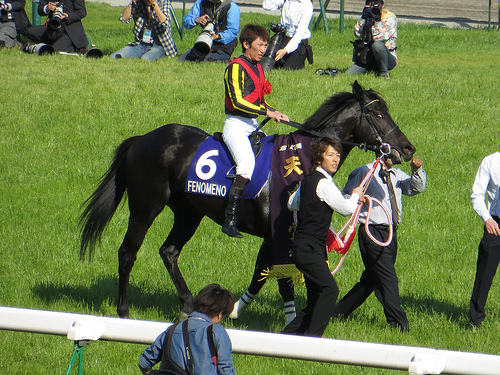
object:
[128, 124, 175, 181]
fur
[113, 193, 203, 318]
legs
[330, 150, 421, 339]
man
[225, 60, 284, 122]
arm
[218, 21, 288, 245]
man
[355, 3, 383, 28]
camera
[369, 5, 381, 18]
lens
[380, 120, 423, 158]
nose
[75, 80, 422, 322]
horse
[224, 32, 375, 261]
lady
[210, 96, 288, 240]
pants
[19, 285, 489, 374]
grass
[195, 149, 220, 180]
number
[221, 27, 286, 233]
rider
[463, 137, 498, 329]
man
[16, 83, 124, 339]
grass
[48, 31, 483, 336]
ground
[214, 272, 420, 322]
shadow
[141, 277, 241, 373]
man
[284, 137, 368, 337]
man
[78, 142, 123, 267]
tail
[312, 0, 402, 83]
photographer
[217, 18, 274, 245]
jockey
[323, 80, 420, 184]
head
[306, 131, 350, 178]
head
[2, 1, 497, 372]
field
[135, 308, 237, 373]
shirt